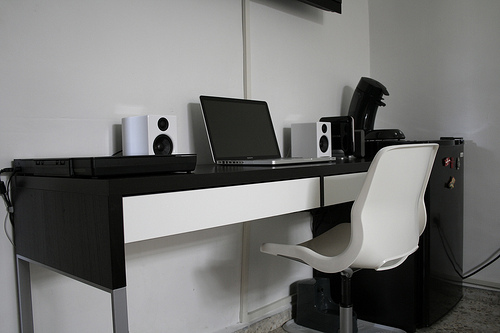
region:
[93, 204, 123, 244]
the table is black and white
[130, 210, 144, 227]
the table is black and white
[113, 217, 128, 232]
the table is black and white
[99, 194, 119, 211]
the table is black and white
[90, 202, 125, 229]
the table is black and white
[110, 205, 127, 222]
the table is black and white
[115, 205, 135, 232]
the table is black and white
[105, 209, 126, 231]
the table is black and white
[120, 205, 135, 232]
the table is black and white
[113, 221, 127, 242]
the table is black and white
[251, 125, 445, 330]
small white desk chair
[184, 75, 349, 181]
small laptop on desk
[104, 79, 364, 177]
computer with speakers on desk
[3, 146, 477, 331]
black and silver computer desk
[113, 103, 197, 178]
small white stereo speakers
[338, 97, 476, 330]
small black personal refrigerator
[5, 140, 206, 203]
small black laptop on desk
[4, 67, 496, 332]
computer equipment on desk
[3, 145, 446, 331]
small metal computer desk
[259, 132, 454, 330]
plastic and metal desk chair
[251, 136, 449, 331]
The chair is white.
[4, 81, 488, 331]
A laptop on a desk.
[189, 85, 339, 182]
The laptop is open.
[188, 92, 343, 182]
The laptop is off.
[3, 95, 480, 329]
The desk is black.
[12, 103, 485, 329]
Desk has two drawers.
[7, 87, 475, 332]
Drawer fronts are white.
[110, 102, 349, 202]
The speakers are white.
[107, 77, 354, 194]
Speakers on each side of laptop.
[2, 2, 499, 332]
The wall is white.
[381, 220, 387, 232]
the stool is white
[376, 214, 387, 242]
the stool is white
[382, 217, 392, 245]
the stool is white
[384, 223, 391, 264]
the stool is white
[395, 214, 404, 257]
the stool is white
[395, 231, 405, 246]
the stool is white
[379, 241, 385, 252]
the stool is white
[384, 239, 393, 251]
the stool is white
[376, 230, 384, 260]
the stool is white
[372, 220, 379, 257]
the stool is white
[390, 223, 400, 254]
the stool is white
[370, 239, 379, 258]
the stool is white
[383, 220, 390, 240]
the stool is white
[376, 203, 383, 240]
the stool is white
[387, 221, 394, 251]
the stool is white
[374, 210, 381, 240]
the stool is white